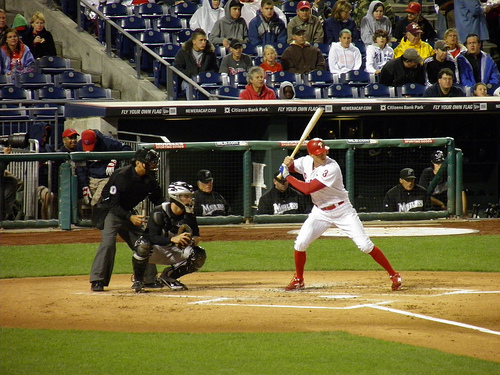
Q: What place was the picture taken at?
A: It was taken at the field.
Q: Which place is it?
A: It is a field.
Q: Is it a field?
A: Yes, it is a field.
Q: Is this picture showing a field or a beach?
A: It is showing a field.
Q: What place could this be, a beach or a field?
A: It is a field.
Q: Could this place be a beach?
A: No, it is a field.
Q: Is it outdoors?
A: Yes, it is outdoors.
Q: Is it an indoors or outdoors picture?
A: It is outdoors.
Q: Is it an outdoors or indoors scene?
A: It is outdoors.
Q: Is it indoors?
A: No, it is outdoors.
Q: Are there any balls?
A: No, there are no balls.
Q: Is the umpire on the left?
A: Yes, the umpire is on the left of the image.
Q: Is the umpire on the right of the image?
A: No, the umpire is on the left of the image.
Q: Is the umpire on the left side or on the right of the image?
A: The umpire is on the left of the image.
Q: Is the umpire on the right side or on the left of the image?
A: The umpire is on the left of the image.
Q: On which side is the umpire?
A: The umpire is on the left of the image.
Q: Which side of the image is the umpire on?
A: The umpire is on the left of the image.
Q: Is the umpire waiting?
A: Yes, the umpire is waiting.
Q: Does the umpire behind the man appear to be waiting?
A: Yes, the umpire is waiting.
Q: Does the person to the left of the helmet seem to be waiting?
A: Yes, the umpire is waiting.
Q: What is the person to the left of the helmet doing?
A: The umpire is waiting.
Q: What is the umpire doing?
A: The umpire is waiting.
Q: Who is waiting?
A: The umpire is waiting.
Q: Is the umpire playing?
A: No, the umpire is waiting.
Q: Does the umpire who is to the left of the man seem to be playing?
A: No, the umpire is waiting.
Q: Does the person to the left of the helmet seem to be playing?
A: No, the umpire is waiting.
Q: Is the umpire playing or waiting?
A: The umpire is waiting.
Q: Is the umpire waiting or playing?
A: The umpire is waiting.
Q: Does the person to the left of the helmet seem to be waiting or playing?
A: The umpire is waiting.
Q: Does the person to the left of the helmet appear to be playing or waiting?
A: The umpire is waiting.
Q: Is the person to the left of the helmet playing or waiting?
A: The umpire is waiting.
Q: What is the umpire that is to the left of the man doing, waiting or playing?
A: The umpire is waiting.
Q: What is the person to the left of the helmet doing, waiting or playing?
A: The umpire is waiting.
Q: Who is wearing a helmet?
A: The umpire is wearing a helmet.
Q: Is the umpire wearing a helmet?
A: Yes, the umpire is wearing a helmet.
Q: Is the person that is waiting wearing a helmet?
A: Yes, the umpire is wearing a helmet.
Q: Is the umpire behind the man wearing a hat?
A: No, the umpire is wearing a helmet.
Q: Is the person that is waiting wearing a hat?
A: No, the umpire is wearing a helmet.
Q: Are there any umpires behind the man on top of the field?
A: Yes, there is an umpire behind the man.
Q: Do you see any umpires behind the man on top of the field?
A: Yes, there is an umpire behind the man.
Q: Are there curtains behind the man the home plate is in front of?
A: No, there is an umpire behind the man.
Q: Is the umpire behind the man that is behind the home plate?
A: Yes, the umpire is behind the man.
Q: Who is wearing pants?
A: The umpire is wearing pants.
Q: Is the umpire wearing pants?
A: Yes, the umpire is wearing pants.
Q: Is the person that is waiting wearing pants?
A: Yes, the umpire is wearing pants.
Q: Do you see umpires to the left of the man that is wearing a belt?
A: Yes, there is an umpire to the left of the man.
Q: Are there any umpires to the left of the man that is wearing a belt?
A: Yes, there is an umpire to the left of the man.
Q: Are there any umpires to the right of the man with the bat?
A: No, the umpire is to the left of the man.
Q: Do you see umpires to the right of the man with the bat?
A: No, the umpire is to the left of the man.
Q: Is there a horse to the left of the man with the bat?
A: No, there is an umpire to the left of the man.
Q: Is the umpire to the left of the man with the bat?
A: Yes, the umpire is to the left of the man.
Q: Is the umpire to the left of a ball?
A: No, the umpire is to the left of the man.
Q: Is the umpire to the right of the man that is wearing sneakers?
A: No, the umpire is to the left of the man.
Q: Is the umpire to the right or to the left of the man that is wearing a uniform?
A: The umpire is to the left of the man.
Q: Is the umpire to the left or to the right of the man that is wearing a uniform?
A: The umpire is to the left of the man.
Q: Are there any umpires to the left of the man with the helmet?
A: Yes, there is an umpire to the left of the man.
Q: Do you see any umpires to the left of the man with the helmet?
A: Yes, there is an umpire to the left of the man.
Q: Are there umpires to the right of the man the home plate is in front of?
A: No, the umpire is to the left of the man.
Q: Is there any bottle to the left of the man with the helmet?
A: No, there is an umpire to the left of the man.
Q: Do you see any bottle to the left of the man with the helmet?
A: No, there is an umpire to the left of the man.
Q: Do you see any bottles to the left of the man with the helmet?
A: No, there is an umpire to the left of the man.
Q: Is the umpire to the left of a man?
A: Yes, the umpire is to the left of a man.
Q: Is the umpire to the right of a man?
A: No, the umpire is to the left of a man.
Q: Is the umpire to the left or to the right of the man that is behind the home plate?
A: The umpire is to the left of the man.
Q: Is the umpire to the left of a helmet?
A: Yes, the umpire is to the left of a helmet.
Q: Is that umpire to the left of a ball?
A: No, the umpire is to the left of a helmet.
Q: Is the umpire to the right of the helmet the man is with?
A: No, the umpire is to the left of the helmet.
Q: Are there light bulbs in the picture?
A: No, there are no light bulbs.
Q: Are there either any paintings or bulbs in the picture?
A: No, there are no bulbs or paintings.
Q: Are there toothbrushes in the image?
A: No, there are no toothbrushes.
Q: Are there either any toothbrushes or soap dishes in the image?
A: No, there are no toothbrushes or soap dishes.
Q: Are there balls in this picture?
A: No, there are no balls.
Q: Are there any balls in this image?
A: No, there are no balls.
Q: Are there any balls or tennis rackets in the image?
A: No, there are no balls or tennis rackets.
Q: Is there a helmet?
A: Yes, there is a helmet.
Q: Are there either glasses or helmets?
A: Yes, there is a helmet.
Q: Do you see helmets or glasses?
A: Yes, there is a helmet.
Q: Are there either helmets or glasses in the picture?
A: Yes, there is a helmet.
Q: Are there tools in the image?
A: No, there are no tools.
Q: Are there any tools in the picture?
A: No, there are no tools.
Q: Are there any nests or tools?
A: No, there are no tools or nests.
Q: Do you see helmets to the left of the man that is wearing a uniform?
A: Yes, there is a helmet to the left of the man.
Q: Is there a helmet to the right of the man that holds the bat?
A: No, the helmet is to the left of the man.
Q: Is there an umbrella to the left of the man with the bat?
A: No, there is a helmet to the left of the man.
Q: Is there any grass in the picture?
A: Yes, there is grass.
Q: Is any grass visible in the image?
A: Yes, there is grass.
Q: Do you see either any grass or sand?
A: Yes, there is grass.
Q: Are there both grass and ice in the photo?
A: No, there is grass but no ice.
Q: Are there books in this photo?
A: No, there are no books.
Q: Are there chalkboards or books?
A: No, there are no books or chalkboards.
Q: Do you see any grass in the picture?
A: Yes, there is grass.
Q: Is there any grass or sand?
A: Yes, there is grass.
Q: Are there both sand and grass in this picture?
A: No, there is grass but no sand.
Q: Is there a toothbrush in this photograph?
A: No, there are no toothbrushes.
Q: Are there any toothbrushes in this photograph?
A: No, there are no toothbrushes.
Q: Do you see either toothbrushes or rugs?
A: No, there are no toothbrushes or rugs.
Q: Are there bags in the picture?
A: No, there are no bags.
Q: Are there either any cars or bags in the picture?
A: No, there are no bags or cars.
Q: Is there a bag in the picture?
A: No, there are no bags.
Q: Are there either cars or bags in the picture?
A: No, there are no bags or cars.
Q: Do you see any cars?
A: No, there are no cars.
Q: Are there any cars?
A: No, there are no cars.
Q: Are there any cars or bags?
A: No, there are no cars or bags.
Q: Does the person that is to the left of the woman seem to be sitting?
A: Yes, the person is sitting.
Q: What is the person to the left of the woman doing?
A: The person is sitting.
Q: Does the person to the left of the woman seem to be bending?
A: No, the person is sitting.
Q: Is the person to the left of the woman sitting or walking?
A: The person is sitting.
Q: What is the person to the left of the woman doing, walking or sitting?
A: The person is sitting.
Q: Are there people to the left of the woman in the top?
A: Yes, there is a person to the left of the woman.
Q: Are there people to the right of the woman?
A: No, the person is to the left of the woman.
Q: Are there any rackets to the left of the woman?
A: No, there is a person to the left of the woman.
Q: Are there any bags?
A: No, there are no bags.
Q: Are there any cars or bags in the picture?
A: No, there are no bags or cars.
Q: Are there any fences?
A: Yes, there is a fence.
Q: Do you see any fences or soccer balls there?
A: Yes, there is a fence.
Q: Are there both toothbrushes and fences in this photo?
A: No, there is a fence but no toothbrushes.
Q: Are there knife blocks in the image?
A: No, there are no knife blocks.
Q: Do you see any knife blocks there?
A: No, there are no knife blocks.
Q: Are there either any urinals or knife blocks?
A: No, there are no knife blocks or urinals.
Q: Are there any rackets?
A: No, there are no rackets.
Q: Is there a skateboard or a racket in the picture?
A: No, there are no rackets or skateboards.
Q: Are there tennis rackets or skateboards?
A: No, there are no tennis rackets or skateboards.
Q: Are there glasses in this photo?
A: No, there are no glasses.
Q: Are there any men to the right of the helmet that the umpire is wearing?
A: Yes, there is a man to the right of the helmet.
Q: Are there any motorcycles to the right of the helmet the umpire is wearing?
A: No, there is a man to the right of the helmet.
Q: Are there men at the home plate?
A: Yes, there is a man at the home plate.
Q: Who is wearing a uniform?
A: The man is wearing a uniform.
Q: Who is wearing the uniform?
A: The man is wearing a uniform.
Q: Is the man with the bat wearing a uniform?
A: Yes, the man is wearing a uniform.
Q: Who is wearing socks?
A: The man is wearing socks.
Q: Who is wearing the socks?
A: The man is wearing socks.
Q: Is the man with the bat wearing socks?
A: Yes, the man is wearing socks.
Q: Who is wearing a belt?
A: The man is wearing a belt.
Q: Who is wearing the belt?
A: The man is wearing a belt.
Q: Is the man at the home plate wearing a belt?
A: Yes, the man is wearing a belt.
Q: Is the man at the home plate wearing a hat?
A: No, the man is wearing a belt.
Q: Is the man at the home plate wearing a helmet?
A: Yes, the man is wearing a helmet.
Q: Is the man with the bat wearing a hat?
A: No, the man is wearing a helmet.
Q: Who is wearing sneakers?
A: The man is wearing sneakers.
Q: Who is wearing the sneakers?
A: The man is wearing sneakers.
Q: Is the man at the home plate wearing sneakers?
A: Yes, the man is wearing sneakers.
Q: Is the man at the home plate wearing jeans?
A: No, the man is wearing sneakers.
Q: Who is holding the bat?
A: The man is holding the bat.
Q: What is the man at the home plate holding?
A: The man is holding the bat.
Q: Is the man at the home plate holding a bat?
A: Yes, the man is holding a bat.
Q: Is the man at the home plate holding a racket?
A: No, the man is holding a bat.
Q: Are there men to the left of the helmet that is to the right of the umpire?
A: No, the man is to the right of the helmet.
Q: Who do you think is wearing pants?
A: The man is wearing pants.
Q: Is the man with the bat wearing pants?
A: Yes, the man is wearing pants.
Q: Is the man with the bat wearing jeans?
A: No, the man is wearing pants.